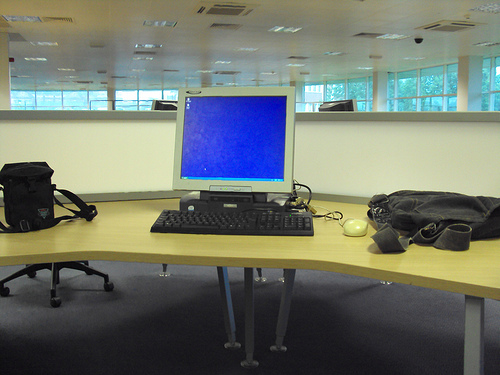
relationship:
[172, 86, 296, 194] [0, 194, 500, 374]
monitor on desk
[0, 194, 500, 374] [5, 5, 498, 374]
desk in office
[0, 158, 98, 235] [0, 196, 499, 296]
bag on desk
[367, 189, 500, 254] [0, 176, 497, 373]
backpack on desk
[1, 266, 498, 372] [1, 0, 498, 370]
floor in room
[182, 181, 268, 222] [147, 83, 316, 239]
cpu of computer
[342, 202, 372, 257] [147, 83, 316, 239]
mouse connected to computer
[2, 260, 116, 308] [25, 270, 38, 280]
chair legs with wheel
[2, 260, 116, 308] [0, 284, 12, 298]
chair legs with wheel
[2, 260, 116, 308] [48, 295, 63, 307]
chair legs with wheel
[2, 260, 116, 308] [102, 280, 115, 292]
chair legs with wheel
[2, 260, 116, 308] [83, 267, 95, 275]
chair legs with wheel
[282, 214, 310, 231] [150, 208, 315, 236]
keypad of computer keyboard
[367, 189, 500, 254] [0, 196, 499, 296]
backpack on desk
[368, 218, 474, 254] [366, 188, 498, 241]
straps on bag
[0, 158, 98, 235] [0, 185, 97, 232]
bag has strap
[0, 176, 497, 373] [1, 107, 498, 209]
desk in front of dividing wall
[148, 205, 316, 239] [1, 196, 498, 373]
computer keyboard on table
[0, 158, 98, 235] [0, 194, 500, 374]
bag on desk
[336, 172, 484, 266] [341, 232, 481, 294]
backpack on table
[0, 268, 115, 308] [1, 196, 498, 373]
wheels behind table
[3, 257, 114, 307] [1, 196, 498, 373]
chair behind table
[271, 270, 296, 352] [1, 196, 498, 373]
leg on table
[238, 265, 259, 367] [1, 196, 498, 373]
leg on table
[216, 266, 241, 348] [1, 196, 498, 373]
leg on table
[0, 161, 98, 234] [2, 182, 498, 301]
bag on desk